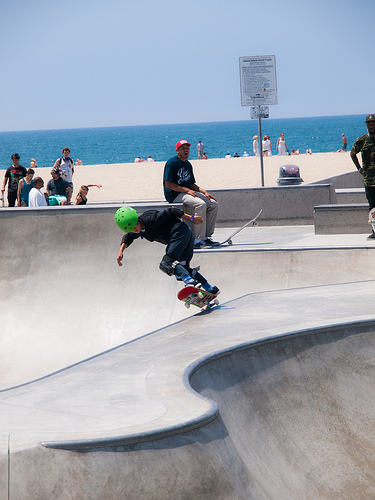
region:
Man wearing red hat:
[161, 138, 221, 251]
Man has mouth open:
[160, 138, 222, 247]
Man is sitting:
[159, 139, 222, 249]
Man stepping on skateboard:
[162, 138, 220, 252]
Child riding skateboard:
[111, 206, 221, 296]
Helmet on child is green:
[113, 206, 138, 233]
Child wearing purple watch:
[116, 206, 224, 298]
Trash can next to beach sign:
[274, 161, 306, 183]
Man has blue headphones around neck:
[50, 144, 75, 198]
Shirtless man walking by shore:
[339, 130, 347, 150]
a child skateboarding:
[29, 88, 336, 337]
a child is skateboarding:
[54, 138, 324, 389]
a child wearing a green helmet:
[76, 176, 342, 363]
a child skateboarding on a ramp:
[93, 170, 338, 382]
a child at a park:
[44, 185, 370, 390]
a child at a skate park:
[87, 183, 313, 339]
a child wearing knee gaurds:
[62, 157, 373, 349]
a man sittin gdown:
[126, 127, 294, 295]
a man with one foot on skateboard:
[157, 114, 309, 320]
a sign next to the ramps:
[224, 25, 372, 226]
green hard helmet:
[103, 195, 158, 250]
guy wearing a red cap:
[164, 128, 203, 161]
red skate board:
[167, 276, 261, 332]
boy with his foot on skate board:
[208, 200, 278, 253]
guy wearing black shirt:
[103, 183, 228, 307]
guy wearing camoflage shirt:
[337, 112, 373, 204]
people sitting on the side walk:
[4, 139, 122, 229]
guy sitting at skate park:
[144, 128, 249, 257]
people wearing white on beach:
[236, 117, 306, 177]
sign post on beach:
[232, 38, 305, 191]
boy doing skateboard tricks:
[105, 201, 235, 324]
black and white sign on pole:
[228, 42, 294, 181]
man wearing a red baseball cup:
[159, 135, 225, 218]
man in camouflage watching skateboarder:
[351, 111, 374, 235]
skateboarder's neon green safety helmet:
[105, 195, 150, 244]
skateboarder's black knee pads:
[158, 252, 181, 274]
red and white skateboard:
[172, 278, 228, 319]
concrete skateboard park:
[50, 324, 366, 455]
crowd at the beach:
[6, 146, 114, 225]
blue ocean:
[106, 119, 162, 153]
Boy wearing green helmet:
[109, 205, 222, 311]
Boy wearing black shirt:
[112, 207, 220, 312]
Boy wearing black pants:
[113, 208, 220, 311]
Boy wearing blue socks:
[113, 204, 220, 312]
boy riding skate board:
[114, 205, 220, 311]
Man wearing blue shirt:
[159, 139, 219, 246]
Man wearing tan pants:
[166, 145, 223, 247]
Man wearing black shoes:
[162, 139, 218, 247]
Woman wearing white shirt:
[55, 148, 75, 200]